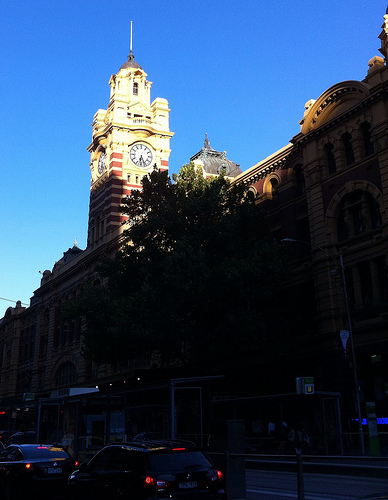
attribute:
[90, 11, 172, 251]
tower — tall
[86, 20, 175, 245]
tower — tall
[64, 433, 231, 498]
car — black 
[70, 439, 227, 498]
car — black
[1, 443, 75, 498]
car — black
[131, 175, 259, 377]
tree — big, green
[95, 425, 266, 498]
car — dark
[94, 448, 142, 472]
window — side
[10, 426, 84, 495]
car — dark